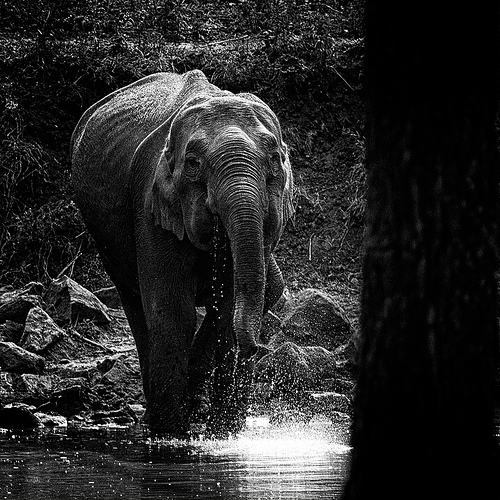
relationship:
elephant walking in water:
[53, 64, 302, 454] [1, 441, 348, 496]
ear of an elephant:
[135, 145, 187, 242] [53, 64, 302, 454]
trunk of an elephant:
[209, 141, 326, 413] [72, 52, 312, 466]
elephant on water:
[53, 64, 302, 454] [43, 420, 361, 497]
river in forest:
[3, 415, 358, 498] [335, 3, 497, 498]